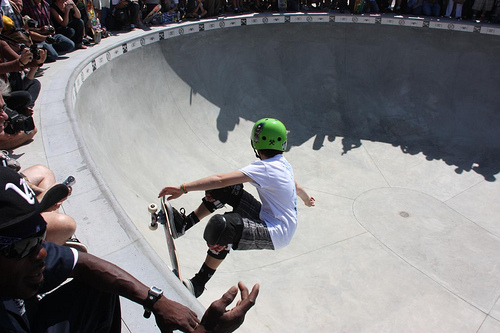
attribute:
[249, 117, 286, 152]
plastic —  green 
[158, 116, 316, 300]
boy — young 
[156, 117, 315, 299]
man — skateboarding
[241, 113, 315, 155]
helmet —  plastic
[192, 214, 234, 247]
pads — knee 